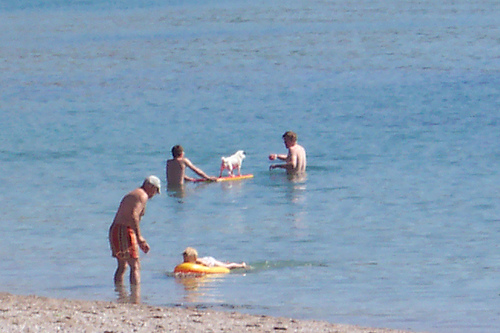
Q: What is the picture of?
A: People playing in water.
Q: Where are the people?
A: In a lake.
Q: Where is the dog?
A: On a floating board.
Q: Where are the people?
A: In the water.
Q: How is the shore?
A: Beach-like.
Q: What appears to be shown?
A: Water.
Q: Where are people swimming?
A: In the ocean.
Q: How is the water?
A: Blue and rippled.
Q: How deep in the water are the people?
A: Waist-deep.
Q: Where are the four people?
A: Swimming in water.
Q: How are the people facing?
A: With their backs turned.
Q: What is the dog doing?
A: Riding.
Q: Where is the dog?
A: On a wakeboard.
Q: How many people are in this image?
A: 4.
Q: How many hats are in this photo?
A: 1.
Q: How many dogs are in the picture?
A: 1.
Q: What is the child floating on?
A: An inner tube.